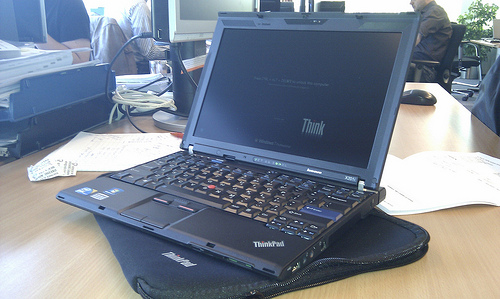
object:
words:
[295, 114, 329, 136]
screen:
[187, 39, 401, 171]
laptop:
[58, 39, 417, 285]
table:
[28, 231, 66, 260]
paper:
[66, 145, 101, 171]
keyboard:
[113, 146, 368, 246]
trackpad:
[141, 188, 180, 227]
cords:
[105, 105, 171, 135]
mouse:
[386, 83, 445, 108]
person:
[90, 11, 116, 56]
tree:
[447, 1, 499, 39]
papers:
[129, 118, 164, 144]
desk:
[422, 240, 425, 255]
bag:
[8, 93, 113, 161]